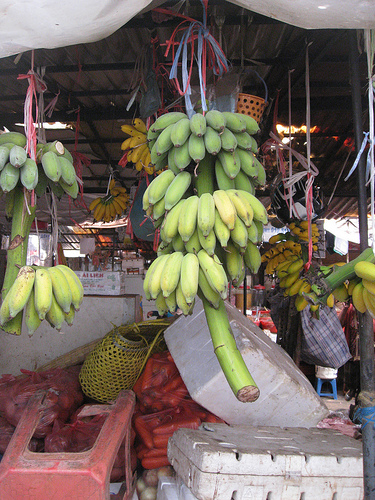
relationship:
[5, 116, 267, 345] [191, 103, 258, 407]
bananas on stalk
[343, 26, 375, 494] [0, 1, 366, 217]
beams on ceiling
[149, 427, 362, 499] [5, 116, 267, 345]
crate under bananas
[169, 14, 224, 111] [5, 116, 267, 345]
ribbon over bananas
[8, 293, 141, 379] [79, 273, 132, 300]
wall under sign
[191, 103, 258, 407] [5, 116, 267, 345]
stalk of bananas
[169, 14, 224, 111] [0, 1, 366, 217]
ribbon on ceiling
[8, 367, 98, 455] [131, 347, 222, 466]
bag of carrots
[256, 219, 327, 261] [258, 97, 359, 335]
menu on wall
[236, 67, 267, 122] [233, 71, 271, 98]
basket has blue handle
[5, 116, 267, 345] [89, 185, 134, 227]
bananas in bunches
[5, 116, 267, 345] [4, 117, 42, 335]
bananas on stalk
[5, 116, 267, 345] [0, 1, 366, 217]
bananas under ceiling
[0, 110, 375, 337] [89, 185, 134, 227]
bananas in bunches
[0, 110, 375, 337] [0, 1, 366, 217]
bananas from ceiling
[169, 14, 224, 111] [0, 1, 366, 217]
ribbon from ceiling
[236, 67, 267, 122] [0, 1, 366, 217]
basket hanging from ceiling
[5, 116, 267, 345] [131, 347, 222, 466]
bananas and carrots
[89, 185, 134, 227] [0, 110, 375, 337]
bunches of bananas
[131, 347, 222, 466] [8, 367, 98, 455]
carrots in bag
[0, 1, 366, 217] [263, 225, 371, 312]
ceiling has bananas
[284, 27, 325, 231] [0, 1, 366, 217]
ribbon on ceiling